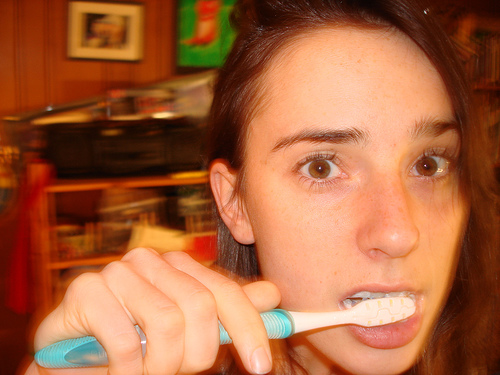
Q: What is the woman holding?
A: Toothbrush.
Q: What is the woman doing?
A: Brushing her teeth.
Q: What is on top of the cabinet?
A: Stereo.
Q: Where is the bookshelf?
A: On the far wall.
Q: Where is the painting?
A: On the wall behind the girl.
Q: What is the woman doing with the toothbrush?
A: Brushing her teeth.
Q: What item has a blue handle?
A: The toothbrush.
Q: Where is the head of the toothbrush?
A: In the girl's mouth.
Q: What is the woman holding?
A: A brush.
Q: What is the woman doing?
A: Brushing.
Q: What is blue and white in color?
A: A toothbrush.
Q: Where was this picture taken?
A: Inside a room.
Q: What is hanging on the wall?
A: A photo frame.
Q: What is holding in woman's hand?
A: A toothbrush.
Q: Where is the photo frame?
A: On the wall.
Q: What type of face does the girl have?
A: An Oval Face.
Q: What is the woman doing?
A: Brushing her teeth.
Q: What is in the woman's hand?
A: A toothbrush.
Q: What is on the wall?
A: A photo.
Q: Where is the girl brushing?
A: In her bedroom.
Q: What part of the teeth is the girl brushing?
A: The front teeth.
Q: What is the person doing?
A: Brushing teeth.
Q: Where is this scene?
A: House.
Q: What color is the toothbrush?
A: Blue and white.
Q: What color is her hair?
A: Auburn.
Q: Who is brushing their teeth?
A: Female.